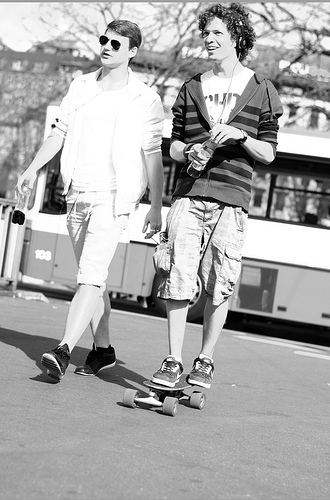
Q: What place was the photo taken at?
A: It was taken at the street.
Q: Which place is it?
A: It is a street.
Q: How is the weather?
A: It is clear.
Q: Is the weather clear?
A: Yes, it is clear.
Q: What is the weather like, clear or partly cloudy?
A: It is clear.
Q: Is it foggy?
A: No, it is clear.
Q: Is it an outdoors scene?
A: Yes, it is outdoors.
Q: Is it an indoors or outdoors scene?
A: It is outdoors.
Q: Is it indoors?
A: No, it is outdoors.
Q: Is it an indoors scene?
A: No, it is outdoors.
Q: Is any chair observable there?
A: No, there are no chairs.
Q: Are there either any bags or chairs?
A: No, there are no chairs or bags.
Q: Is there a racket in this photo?
A: No, there are no rackets.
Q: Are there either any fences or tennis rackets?
A: No, there are no tennis rackets or fences.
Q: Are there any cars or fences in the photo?
A: No, there are no cars or fences.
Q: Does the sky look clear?
A: Yes, the sky is clear.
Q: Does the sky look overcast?
A: No, the sky is clear.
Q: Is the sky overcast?
A: No, the sky is clear.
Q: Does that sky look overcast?
A: No, the sky is clear.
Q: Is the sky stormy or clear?
A: The sky is clear.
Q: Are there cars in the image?
A: No, there are no cars.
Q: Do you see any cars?
A: No, there are no cars.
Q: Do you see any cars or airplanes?
A: No, there are no cars or airplanes.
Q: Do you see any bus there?
A: Yes, there is a bus.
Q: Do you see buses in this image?
A: Yes, there is a bus.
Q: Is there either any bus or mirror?
A: Yes, there is a bus.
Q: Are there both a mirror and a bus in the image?
A: No, there is a bus but no mirrors.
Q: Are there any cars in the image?
A: No, there are no cars.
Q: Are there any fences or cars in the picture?
A: No, there are no cars or fences.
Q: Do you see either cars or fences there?
A: No, there are no cars or fences.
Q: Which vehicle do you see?
A: The vehicle is a bus.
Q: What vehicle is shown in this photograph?
A: The vehicle is a bus.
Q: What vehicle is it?
A: The vehicle is a bus.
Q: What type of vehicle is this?
A: This is a bus.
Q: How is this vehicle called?
A: This is a bus.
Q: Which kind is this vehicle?
A: This is a bus.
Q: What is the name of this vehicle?
A: This is a bus.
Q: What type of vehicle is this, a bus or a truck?
A: This is a bus.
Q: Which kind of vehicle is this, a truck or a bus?
A: This is a bus.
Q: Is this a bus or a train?
A: This is a bus.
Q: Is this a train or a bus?
A: This is a bus.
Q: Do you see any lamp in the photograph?
A: No, there are no lamps.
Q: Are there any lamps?
A: No, there are no lamps.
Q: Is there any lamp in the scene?
A: No, there are no lamps.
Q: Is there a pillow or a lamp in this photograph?
A: No, there are no lamps or pillows.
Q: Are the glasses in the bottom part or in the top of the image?
A: The glasses are in the top of the image.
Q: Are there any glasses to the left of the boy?
A: Yes, there are glasses to the left of the boy.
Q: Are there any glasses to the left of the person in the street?
A: Yes, there are glasses to the left of the boy.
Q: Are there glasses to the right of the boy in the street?
A: No, the glasses are to the left of the boy.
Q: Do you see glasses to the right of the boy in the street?
A: No, the glasses are to the left of the boy.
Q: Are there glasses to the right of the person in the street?
A: No, the glasses are to the left of the boy.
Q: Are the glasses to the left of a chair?
A: No, the glasses are to the left of the boy.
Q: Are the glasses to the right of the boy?
A: No, the glasses are to the left of the boy.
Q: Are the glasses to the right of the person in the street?
A: No, the glasses are to the left of the boy.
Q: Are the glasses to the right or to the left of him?
A: The glasses are to the left of the boy.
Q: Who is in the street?
A: The boy is in the street.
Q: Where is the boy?
A: The boy is in the street.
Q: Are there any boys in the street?
A: Yes, there is a boy in the street.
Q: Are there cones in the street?
A: No, there is a boy in the street.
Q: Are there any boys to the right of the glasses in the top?
A: Yes, there is a boy to the right of the glasses.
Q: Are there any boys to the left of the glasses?
A: No, the boy is to the right of the glasses.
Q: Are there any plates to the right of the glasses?
A: No, there is a boy to the right of the glasses.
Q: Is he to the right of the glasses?
A: Yes, the boy is to the right of the glasses.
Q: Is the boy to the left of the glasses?
A: No, the boy is to the right of the glasses.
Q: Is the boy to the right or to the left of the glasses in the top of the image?
A: The boy is to the right of the glasses.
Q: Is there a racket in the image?
A: No, there are no rackets.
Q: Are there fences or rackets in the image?
A: No, there are no rackets or fences.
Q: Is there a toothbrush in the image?
A: No, there are no toothbrushes.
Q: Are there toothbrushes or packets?
A: No, there are no toothbrushes or packets.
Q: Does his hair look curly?
A: Yes, the hair is curly.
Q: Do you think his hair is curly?
A: Yes, the hair is curly.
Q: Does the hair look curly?
A: Yes, the hair is curly.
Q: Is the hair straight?
A: No, the hair is curly.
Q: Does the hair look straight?
A: No, the hair is curly.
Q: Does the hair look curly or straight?
A: The hair is curly.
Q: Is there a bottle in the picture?
A: Yes, there is a bottle.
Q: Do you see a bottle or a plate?
A: Yes, there is a bottle.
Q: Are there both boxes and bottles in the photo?
A: No, there is a bottle but no boxes.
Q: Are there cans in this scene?
A: No, there are no cans.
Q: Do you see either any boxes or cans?
A: No, there are no cans or boxes.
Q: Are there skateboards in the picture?
A: Yes, there is a skateboard.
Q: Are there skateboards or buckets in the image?
A: Yes, there is a skateboard.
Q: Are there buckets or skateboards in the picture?
A: Yes, there is a skateboard.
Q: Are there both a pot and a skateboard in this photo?
A: No, there is a skateboard but no pots.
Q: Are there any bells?
A: No, there are no bells.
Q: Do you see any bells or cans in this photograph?
A: No, there are no bells or cans.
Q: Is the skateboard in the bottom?
A: Yes, the skateboard is in the bottom of the image.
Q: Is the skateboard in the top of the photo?
A: No, the skateboard is in the bottom of the image.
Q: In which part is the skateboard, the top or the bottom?
A: The skateboard is in the bottom of the image.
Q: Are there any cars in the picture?
A: No, there are no cars.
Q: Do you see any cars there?
A: No, there are no cars.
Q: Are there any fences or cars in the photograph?
A: No, there are no cars or fences.